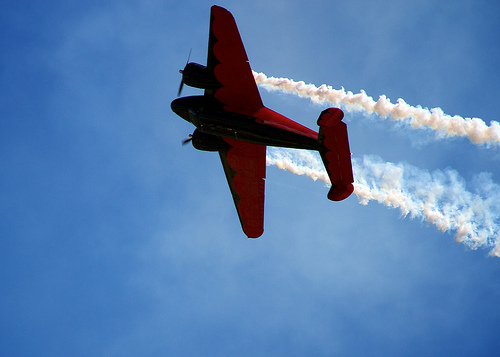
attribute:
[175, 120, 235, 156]
engine — small, black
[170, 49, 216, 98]
engine — black, small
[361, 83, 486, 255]
smoke — white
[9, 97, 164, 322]
sky — blue, clear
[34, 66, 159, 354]
sky — blue, clear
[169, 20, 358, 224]
airplane — red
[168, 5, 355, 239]
airplane — red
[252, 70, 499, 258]
smoke — white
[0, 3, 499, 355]
sky — blue, clear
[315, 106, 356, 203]
tail — red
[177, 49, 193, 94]
propeller — spinning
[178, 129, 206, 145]
propeller — spinning